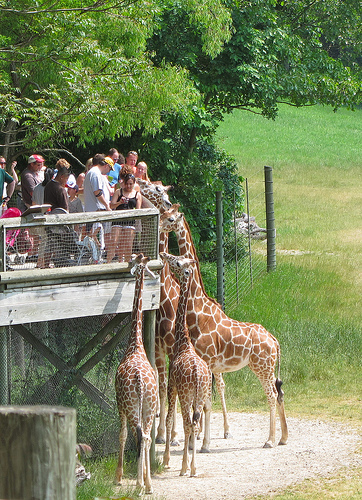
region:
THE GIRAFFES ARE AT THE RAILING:
[108, 172, 290, 498]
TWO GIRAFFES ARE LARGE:
[132, 168, 289, 453]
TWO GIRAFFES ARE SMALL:
[107, 246, 216, 498]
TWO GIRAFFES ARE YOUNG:
[105, 248, 211, 498]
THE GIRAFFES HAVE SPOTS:
[102, 178, 296, 493]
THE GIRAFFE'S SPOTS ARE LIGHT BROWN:
[110, 176, 294, 497]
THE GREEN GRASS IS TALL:
[198, 260, 359, 420]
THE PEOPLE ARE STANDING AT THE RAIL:
[1, 151, 157, 274]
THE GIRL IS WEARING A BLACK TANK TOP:
[107, 182, 151, 224]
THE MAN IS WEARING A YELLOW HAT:
[101, 151, 119, 175]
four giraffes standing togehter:
[104, 179, 294, 469]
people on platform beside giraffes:
[5, 150, 156, 270]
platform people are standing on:
[4, 199, 160, 461]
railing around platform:
[0, 210, 165, 279]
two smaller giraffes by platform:
[121, 246, 208, 485]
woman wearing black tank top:
[109, 181, 150, 254]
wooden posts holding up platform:
[3, 312, 159, 458]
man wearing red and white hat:
[23, 153, 50, 262]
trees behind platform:
[4, 4, 248, 254]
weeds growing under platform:
[6, 361, 138, 458]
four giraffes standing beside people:
[12, 139, 310, 486]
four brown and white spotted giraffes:
[126, 180, 290, 465]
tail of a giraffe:
[270, 330, 288, 402]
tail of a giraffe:
[190, 355, 207, 434]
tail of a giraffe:
[128, 365, 154, 462]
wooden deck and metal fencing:
[8, 219, 158, 454]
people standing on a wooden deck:
[5, 136, 162, 280]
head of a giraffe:
[121, 244, 159, 291]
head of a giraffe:
[135, 173, 170, 210]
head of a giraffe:
[156, 202, 186, 242]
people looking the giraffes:
[2, 137, 291, 487]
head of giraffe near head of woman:
[116, 165, 174, 216]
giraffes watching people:
[5, 136, 269, 492]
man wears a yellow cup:
[82, 153, 118, 200]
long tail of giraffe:
[270, 334, 292, 410]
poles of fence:
[191, 151, 299, 306]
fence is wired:
[202, 191, 287, 301]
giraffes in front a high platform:
[9, 145, 305, 496]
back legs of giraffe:
[253, 368, 296, 453]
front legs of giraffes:
[204, 374, 228, 439]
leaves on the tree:
[83, 60, 182, 124]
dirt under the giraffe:
[219, 439, 262, 487]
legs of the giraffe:
[253, 406, 301, 454]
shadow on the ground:
[214, 437, 247, 468]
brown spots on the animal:
[205, 322, 255, 362]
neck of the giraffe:
[159, 275, 208, 341]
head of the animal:
[154, 246, 195, 289]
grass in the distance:
[282, 115, 338, 156]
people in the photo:
[13, 149, 152, 226]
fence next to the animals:
[208, 158, 297, 319]